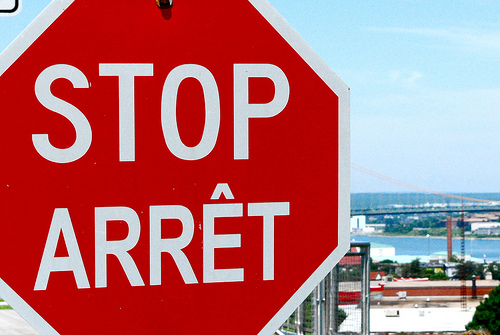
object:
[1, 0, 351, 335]
sign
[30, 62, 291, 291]
letters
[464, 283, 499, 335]
tree top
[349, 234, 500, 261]
water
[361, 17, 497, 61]
clouds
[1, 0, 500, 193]
sky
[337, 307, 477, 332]
roof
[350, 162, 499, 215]
bridge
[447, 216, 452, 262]
columns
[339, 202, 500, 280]
buildings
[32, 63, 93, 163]
s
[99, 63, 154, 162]
t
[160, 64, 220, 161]
o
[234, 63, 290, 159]
p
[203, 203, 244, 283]
e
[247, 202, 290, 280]
t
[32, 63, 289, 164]
stop